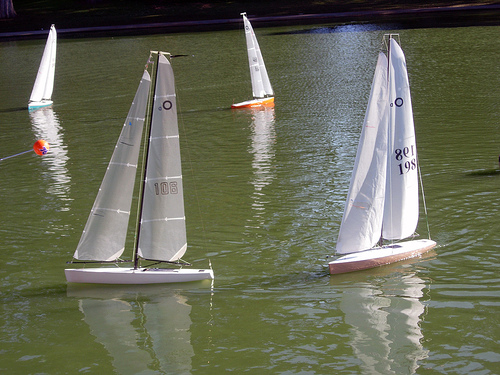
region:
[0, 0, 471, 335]
four toy boats in the water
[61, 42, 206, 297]
a toy boat floating in the water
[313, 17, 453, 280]
a toy boat with a white sail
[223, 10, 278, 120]
a orange boat with a white sail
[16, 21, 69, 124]
a green boat with a white sail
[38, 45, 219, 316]
a white boat with a white sail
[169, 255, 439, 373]
body of green water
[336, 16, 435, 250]
a white sail with numbers printed on it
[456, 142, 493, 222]
a shadow on the water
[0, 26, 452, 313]
four toy boats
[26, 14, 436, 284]
a fleet of small toy sail boats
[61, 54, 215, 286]
a white sail boat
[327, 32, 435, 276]
a pink sail boat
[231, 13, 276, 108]
an orange sail boat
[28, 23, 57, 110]
a blue sail boat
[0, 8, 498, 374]
green pond water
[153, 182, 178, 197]
numbers on the white boats sail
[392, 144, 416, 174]
numbers on the pink boats sail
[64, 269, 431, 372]
reflections of the boats in the water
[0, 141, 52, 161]
boat antenna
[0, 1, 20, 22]
large brown tree trunk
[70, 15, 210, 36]
gray concrete ledge at waters edge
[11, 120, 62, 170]
flying orange fishing bobber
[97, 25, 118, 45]
small green turtle's head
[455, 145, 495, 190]
black fish hovering just under water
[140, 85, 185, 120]
black circle on white sail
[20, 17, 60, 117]
small green sailboat with no number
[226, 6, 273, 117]
small orange sailboat with no number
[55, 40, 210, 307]
white sailboat number 106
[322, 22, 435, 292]
pink sailboat number 198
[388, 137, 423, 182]
backwards numbers on white sail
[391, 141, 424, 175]
black numbers on white sail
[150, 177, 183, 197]
red-edged numbers on clear sail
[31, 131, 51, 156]
orange and yellow ball floating in water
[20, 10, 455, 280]
4 toy sailboats in water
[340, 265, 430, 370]
boat's reflection in water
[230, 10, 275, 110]
orange boat with white sail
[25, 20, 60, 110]
light blue boat with white sail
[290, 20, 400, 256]
sunlight reflected in green water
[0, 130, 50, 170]
white string attached to orange ball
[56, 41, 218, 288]
white sailboat in green water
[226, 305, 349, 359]
patch of green water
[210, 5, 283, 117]
white sailboat with orange base in green water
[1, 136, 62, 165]
red ball attached to white string in green water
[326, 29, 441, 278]
white sail boat with mauve and white base in green water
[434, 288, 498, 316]
dark ripple in green water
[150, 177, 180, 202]
number on white sail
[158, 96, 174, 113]
black circle on white sail in green water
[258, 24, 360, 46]
black shadow on surface of green water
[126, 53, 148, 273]
black pole in center of sailboat